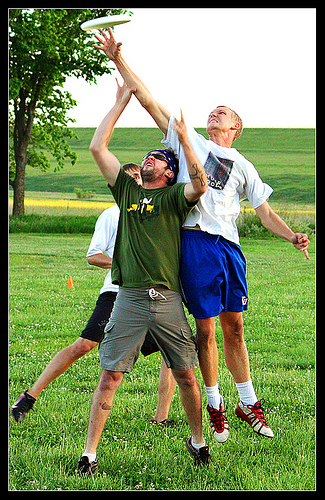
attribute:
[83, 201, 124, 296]
shirt — white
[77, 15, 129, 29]
frisbee — in air, yellow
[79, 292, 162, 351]
shorts — black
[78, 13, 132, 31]
frisbee — white, in air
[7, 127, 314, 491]
grass — green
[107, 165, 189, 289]
tee shirt — green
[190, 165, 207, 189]
tattoo — cross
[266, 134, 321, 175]
grass — green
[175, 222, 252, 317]
shorts — blue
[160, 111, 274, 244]
tee shirt — white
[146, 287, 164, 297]
knot — white, lace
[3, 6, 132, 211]
tree — tall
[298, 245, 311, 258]
finger — extended, pinky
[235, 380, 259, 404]
sock — white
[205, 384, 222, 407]
sock — white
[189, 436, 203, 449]
sock — white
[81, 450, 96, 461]
sock — white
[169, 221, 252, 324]
shorts — blue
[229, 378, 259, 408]
sock — tall, white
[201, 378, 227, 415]
sock — tall, white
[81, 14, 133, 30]
frisby — flying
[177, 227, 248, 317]
shorts — blue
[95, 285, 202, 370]
shorts — grey, gray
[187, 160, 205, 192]
tattoo — cross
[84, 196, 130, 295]
shirt — white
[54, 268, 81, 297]
cone — small, orange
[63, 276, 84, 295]
cone — orange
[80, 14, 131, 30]
frisbie — white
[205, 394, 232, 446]
cleat — red, white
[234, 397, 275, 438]
cleat — red, white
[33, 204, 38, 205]
flower — yellow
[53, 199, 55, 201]
flower — yellow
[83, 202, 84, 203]
flower — yellow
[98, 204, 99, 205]
flower — yellow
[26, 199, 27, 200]
flower — yellow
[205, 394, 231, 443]
athletic shoe — white, red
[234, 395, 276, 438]
athletic shoe — white, red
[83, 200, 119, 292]
shirt — white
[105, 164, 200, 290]
shirt — green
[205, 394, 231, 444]
shoe — red, white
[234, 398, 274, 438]
shoe — white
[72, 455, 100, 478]
shoe — dark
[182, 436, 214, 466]
shoe — dark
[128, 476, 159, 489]
flowers — small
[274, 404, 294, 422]
flowers — small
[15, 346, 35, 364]
flowers — small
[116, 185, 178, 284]
shirt — green